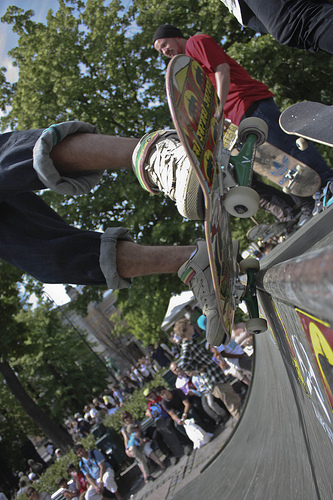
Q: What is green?
A: Trees.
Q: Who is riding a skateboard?
A: A person.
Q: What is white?
A: Wheels of skateboard.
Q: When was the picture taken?
A: Daytime.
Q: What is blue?
A: Sky.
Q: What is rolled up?
A: Skateboarder's pants.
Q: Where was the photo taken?
A: At a skatepark.